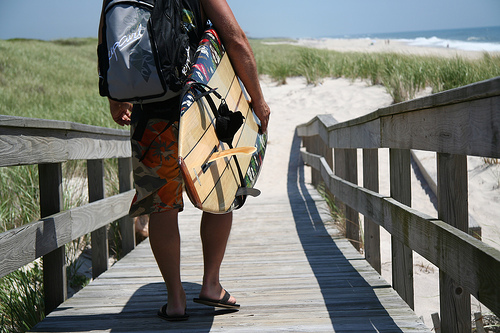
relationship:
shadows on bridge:
[23, 127, 403, 333] [0, 74, 499, 332]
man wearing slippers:
[97, 0, 270, 322] [157, 289, 240, 320]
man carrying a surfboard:
[97, 0, 270, 322] [177, 17, 268, 214]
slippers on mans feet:
[157, 289, 240, 320] [159, 282, 237, 316]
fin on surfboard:
[206, 147, 257, 164] [177, 17, 268, 214]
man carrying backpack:
[97, 0, 270, 322] [97, 0, 191, 105]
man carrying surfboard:
[97, 0, 270, 322] [177, 17, 268, 214]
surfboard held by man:
[177, 17, 268, 214] [97, 0, 270, 322]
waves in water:
[359, 35, 499, 52] [310, 25, 499, 52]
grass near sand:
[0, 38, 498, 331] [0, 37, 499, 333]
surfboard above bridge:
[177, 17, 268, 214] [0, 74, 499, 332]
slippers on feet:
[157, 289, 240, 320] [159, 282, 237, 316]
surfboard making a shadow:
[177, 17, 268, 214] [109, 281, 214, 332]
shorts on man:
[129, 120, 185, 217] [97, 0, 270, 322]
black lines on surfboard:
[180, 48, 250, 205] [177, 17, 268, 214]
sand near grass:
[0, 37, 499, 333] [0, 38, 498, 331]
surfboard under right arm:
[177, 17, 268, 214] [201, 1, 270, 134]